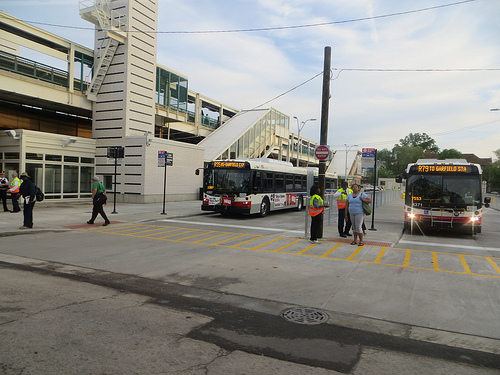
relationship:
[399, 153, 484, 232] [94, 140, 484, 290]
parked bus at bus stop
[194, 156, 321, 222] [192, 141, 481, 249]
bus parked at bus stop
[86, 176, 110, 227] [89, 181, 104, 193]
man wearing a green shirt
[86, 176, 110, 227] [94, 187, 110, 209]
man carrying a black bag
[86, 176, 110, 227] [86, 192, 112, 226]
man wearing black pants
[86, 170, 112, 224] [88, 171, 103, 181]
man has gray hair